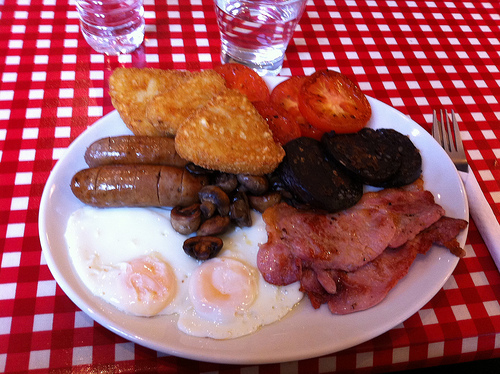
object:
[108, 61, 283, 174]
two has browns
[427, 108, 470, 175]
part of a fork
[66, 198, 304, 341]
two cooked eggs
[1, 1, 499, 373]
tablecloth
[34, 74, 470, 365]
plate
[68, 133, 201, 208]
couple of sausages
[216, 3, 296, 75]
water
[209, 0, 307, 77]
glass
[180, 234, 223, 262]
mushrooms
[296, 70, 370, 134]
tomato slices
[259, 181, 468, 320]
few slices of ham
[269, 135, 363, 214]
food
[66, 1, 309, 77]
two plastic bottles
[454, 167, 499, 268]
napkin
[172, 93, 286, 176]
breakfast food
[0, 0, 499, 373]
table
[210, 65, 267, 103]
tomato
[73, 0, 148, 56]
water bottle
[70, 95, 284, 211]
two types of food